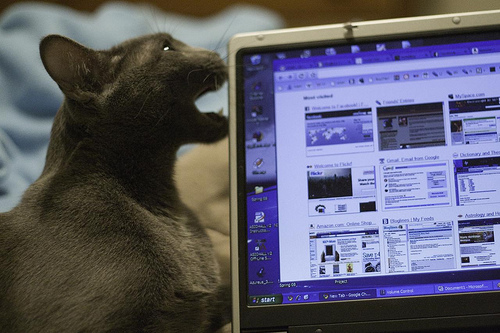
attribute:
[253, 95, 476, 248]
screen — computer, laptop, windows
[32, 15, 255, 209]
cat — gray, hissing, open, vocalizing, sitting, grey, look, dark, laying, opening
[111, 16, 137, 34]
fabric — brown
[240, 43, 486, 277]
monitor — laptop, on, window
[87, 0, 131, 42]
blanket — blue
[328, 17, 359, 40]
latch — plastic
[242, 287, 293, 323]
bar — start, task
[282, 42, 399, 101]
page — preview